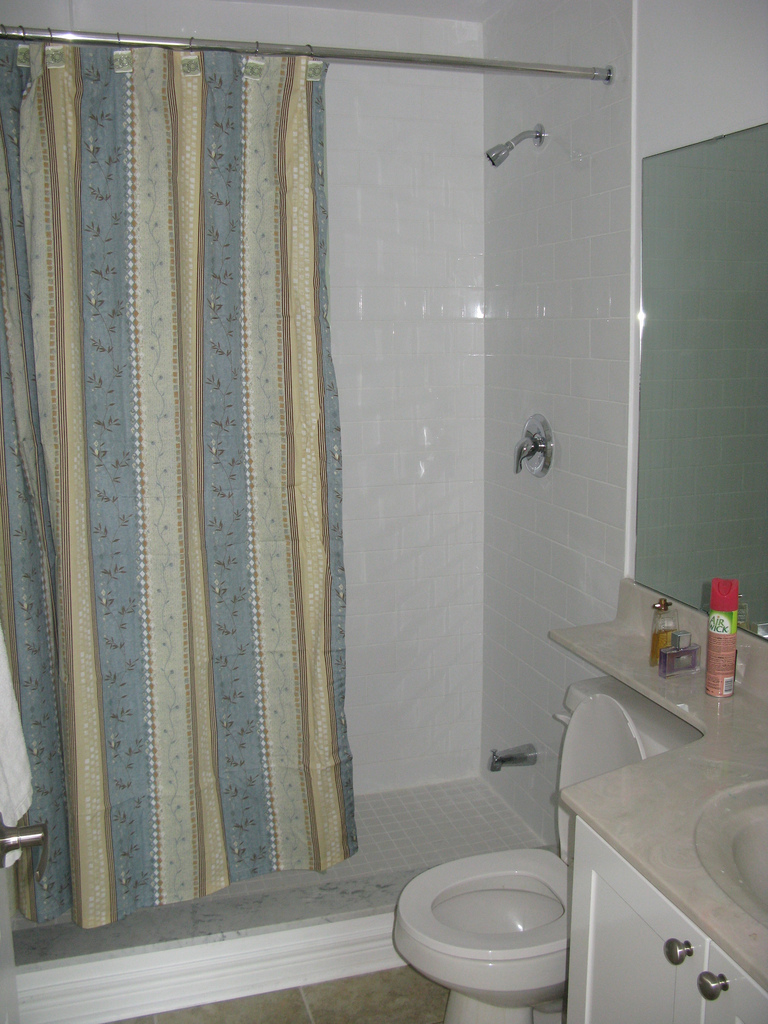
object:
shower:
[4, 37, 637, 955]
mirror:
[633, 118, 768, 641]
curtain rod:
[1, 19, 619, 88]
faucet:
[483, 725, 540, 779]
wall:
[642, 9, 767, 118]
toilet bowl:
[397, 838, 578, 1019]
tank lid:
[557, 676, 705, 762]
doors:
[568, 868, 707, 1021]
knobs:
[695, 959, 733, 1002]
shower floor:
[367, 796, 515, 848]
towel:
[0, 610, 40, 826]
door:
[0, 619, 37, 1008]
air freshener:
[704, 570, 738, 700]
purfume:
[646, 588, 702, 681]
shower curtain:
[17, 32, 340, 939]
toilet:
[393, 690, 654, 1019]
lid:
[555, 682, 650, 862]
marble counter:
[627, 775, 755, 858]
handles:
[659, 934, 702, 966]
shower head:
[481, 115, 553, 176]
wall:
[492, 189, 615, 411]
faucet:
[506, 395, 557, 486]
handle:
[0, 811, 57, 882]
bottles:
[647, 594, 702, 681]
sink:
[733, 802, 767, 879]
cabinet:
[568, 811, 768, 1019]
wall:
[380, 221, 459, 585]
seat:
[389, 840, 569, 991]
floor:
[302, 983, 423, 1021]